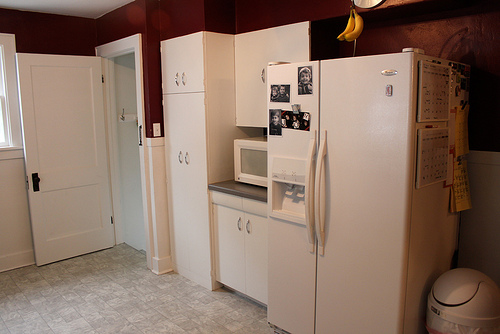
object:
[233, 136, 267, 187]
microwave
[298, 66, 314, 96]
pictures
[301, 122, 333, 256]
handles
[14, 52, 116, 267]
door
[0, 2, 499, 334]
kitchen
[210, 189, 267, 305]
doors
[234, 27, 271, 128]
door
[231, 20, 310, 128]
cabinet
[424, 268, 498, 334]
can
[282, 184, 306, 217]
dispenser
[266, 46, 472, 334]
fridge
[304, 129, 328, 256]
handles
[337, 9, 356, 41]
bananas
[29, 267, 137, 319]
floor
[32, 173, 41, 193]
handle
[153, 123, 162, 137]
switch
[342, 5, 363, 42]
banana